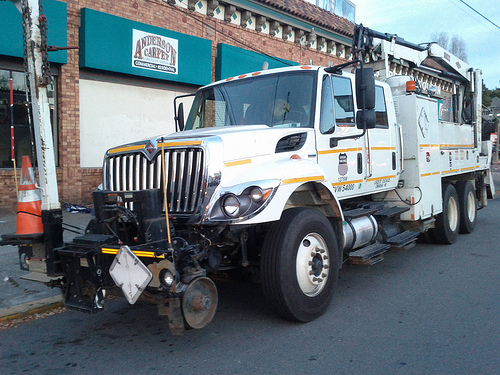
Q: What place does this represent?
A: It represents the road.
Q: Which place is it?
A: It is a road.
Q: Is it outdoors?
A: Yes, it is outdoors.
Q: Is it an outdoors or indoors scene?
A: It is outdoors.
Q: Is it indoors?
A: No, it is outdoors.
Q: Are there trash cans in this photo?
A: No, there are no trash cans.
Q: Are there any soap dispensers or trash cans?
A: No, there are no trash cans or soap dispensers.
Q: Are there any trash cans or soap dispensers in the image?
A: No, there are no trash cans or soap dispensers.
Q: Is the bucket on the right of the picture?
A: Yes, the bucket is on the right of the image.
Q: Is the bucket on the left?
A: No, the bucket is on the right of the image.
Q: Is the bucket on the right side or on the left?
A: The bucket is on the right of the image.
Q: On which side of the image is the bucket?
A: The bucket is on the right of the image.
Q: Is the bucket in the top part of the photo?
A: Yes, the bucket is in the top of the image.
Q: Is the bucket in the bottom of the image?
A: No, the bucket is in the top of the image.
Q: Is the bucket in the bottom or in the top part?
A: The bucket is in the top of the image.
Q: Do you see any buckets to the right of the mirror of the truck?
A: Yes, there is a bucket to the right of the mirror.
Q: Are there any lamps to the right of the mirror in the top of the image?
A: No, there is a bucket to the right of the mirror.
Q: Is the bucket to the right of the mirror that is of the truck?
A: Yes, the bucket is to the right of the mirror.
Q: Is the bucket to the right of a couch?
A: No, the bucket is to the right of the mirror.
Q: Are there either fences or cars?
A: No, there are no fences or cars.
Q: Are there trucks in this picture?
A: Yes, there is a truck.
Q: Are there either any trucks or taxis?
A: Yes, there is a truck.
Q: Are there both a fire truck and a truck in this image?
A: No, there is a truck but no fire trucks.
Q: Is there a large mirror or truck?
A: Yes, there is a large truck.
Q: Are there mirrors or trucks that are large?
A: Yes, the truck is large.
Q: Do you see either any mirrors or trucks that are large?
A: Yes, the truck is large.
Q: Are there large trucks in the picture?
A: Yes, there is a large truck.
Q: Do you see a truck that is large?
A: Yes, there is a large truck.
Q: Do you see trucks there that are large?
A: Yes, there is a truck that is large.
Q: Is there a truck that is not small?
A: Yes, there is a large truck.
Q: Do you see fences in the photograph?
A: No, there are no fences.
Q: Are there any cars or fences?
A: No, there are no fences or cars.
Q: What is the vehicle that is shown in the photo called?
A: The vehicle is a truck.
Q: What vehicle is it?
A: The vehicle is a truck.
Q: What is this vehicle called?
A: This is a truck.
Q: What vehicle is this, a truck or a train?
A: This is a truck.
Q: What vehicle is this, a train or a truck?
A: This is a truck.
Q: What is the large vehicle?
A: The vehicle is a truck.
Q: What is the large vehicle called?
A: The vehicle is a truck.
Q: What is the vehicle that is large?
A: The vehicle is a truck.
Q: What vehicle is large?
A: The vehicle is a truck.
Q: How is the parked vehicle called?
A: The vehicle is a truck.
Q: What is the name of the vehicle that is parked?
A: The vehicle is a truck.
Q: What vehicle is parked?
A: The vehicle is a truck.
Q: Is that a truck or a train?
A: That is a truck.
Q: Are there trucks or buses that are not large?
A: No, there is a truck but it is large.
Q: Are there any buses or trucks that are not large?
A: No, there is a truck but it is large.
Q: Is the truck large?
A: Yes, the truck is large.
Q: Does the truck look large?
A: Yes, the truck is large.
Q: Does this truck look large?
A: Yes, the truck is large.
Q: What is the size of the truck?
A: The truck is large.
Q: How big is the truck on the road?
A: The truck is large.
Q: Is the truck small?
A: No, the truck is large.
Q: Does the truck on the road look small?
A: No, the truck is large.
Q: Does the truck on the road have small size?
A: No, the truck is large.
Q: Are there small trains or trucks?
A: No, there is a truck but it is large.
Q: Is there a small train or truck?
A: No, there is a truck but it is large.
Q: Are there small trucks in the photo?
A: No, there is a truck but it is large.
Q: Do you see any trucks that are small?
A: No, there is a truck but it is large.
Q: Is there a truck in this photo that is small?
A: No, there is a truck but it is large.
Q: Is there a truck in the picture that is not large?
A: No, there is a truck but it is large.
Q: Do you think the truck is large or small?
A: The truck is large.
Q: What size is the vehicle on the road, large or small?
A: The truck is large.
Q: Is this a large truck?
A: Yes, this is a large truck.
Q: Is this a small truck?
A: No, this is a large truck.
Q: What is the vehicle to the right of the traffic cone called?
A: The vehicle is a truck.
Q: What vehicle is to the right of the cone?
A: The vehicle is a truck.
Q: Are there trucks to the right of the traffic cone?
A: Yes, there is a truck to the right of the traffic cone.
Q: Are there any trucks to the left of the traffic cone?
A: No, the truck is to the right of the traffic cone.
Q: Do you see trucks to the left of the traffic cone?
A: No, the truck is to the right of the traffic cone.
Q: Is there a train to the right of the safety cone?
A: No, there is a truck to the right of the safety cone.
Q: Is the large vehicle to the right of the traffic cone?
A: Yes, the truck is to the right of the traffic cone.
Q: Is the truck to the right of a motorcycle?
A: No, the truck is to the right of the traffic cone.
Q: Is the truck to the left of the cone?
A: No, the truck is to the right of the cone.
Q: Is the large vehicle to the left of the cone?
A: No, the truck is to the right of the cone.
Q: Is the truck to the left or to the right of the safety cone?
A: The truck is to the right of the safety cone.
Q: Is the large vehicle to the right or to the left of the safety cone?
A: The truck is to the right of the safety cone.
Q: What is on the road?
A: The truck is on the road.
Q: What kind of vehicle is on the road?
A: The vehicle is a truck.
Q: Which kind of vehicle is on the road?
A: The vehicle is a truck.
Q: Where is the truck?
A: The truck is on the road.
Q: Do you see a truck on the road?
A: Yes, there is a truck on the road.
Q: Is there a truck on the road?
A: Yes, there is a truck on the road.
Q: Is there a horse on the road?
A: No, there is a truck on the road.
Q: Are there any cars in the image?
A: No, there are no cars.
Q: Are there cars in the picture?
A: No, there are no cars.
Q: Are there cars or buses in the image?
A: No, there are no cars or buses.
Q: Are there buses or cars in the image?
A: No, there are no cars or buses.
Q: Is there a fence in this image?
A: No, there are no fences.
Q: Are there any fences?
A: No, there are no fences.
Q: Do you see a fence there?
A: No, there are no fences.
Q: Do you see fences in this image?
A: No, there are no fences.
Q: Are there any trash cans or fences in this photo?
A: No, there are no fences or trash cans.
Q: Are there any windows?
A: Yes, there is a window.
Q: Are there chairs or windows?
A: Yes, there is a window.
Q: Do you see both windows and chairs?
A: No, there is a window but no chairs.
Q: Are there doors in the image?
A: No, there are no doors.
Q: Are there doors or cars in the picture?
A: No, there are no doors or cars.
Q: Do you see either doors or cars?
A: No, there are no doors or cars.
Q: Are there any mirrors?
A: Yes, there is a mirror.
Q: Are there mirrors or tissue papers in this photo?
A: Yes, there is a mirror.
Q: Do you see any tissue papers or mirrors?
A: Yes, there is a mirror.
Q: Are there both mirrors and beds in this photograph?
A: No, there is a mirror but no beds.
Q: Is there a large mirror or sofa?
A: Yes, there is a large mirror.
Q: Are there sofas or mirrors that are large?
A: Yes, the mirror is large.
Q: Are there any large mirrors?
A: Yes, there is a large mirror.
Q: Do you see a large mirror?
A: Yes, there is a large mirror.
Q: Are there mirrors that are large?
A: Yes, there is a mirror that is large.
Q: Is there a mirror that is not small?
A: Yes, there is a large mirror.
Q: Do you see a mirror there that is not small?
A: Yes, there is a large mirror.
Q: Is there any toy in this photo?
A: No, there are no toys.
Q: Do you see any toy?
A: No, there are no toys.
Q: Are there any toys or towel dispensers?
A: No, there are no toys or towel dispensers.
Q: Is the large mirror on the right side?
A: Yes, the mirror is on the right of the image.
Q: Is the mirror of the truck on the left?
A: No, the mirror is on the right of the image.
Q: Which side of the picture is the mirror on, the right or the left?
A: The mirror is on the right of the image.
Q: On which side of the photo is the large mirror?
A: The mirror is on the right of the image.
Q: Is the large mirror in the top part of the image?
A: Yes, the mirror is in the top of the image.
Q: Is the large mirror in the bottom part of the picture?
A: No, the mirror is in the top of the image.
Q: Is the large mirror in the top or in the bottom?
A: The mirror is in the top of the image.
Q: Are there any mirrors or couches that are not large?
A: No, there is a mirror but it is large.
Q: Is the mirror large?
A: Yes, the mirror is large.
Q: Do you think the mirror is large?
A: Yes, the mirror is large.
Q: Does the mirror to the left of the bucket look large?
A: Yes, the mirror is large.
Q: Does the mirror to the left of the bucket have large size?
A: Yes, the mirror is large.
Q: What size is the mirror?
A: The mirror is large.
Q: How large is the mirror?
A: The mirror is large.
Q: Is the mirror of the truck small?
A: No, the mirror is large.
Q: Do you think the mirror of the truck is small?
A: No, the mirror is large.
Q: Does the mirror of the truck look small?
A: No, the mirror is large.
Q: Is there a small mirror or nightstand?
A: No, there is a mirror but it is large.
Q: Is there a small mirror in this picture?
A: No, there is a mirror but it is large.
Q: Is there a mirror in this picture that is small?
A: No, there is a mirror but it is large.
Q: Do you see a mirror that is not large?
A: No, there is a mirror but it is large.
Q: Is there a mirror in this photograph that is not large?
A: No, there is a mirror but it is large.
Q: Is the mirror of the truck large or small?
A: The mirror is large.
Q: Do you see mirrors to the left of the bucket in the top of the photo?
A: Yes, there is a mirror to the left of the bucket.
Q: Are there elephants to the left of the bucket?
A: No, there is a mirror to the left of the bucket.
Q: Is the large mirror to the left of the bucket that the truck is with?
A: Yes, the mirror is to the left of the bucket.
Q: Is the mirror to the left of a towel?
A: No, the mirror is to the left of the bucket.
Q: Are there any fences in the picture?
A: No, there are no fences.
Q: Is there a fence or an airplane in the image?
A: No, there are no fences or airplanes.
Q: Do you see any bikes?
A: No, there are no bikes.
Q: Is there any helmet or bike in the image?
A: No, there are no bikes or helmets.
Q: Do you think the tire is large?
A: Yes, the tire is large.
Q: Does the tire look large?
A: Yes, the tire is large.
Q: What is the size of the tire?
A: The tire is large.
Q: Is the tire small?
A: No, the tire is large.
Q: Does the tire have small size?
A: No, the tire is large.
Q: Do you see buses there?
A: No, there are no buses.